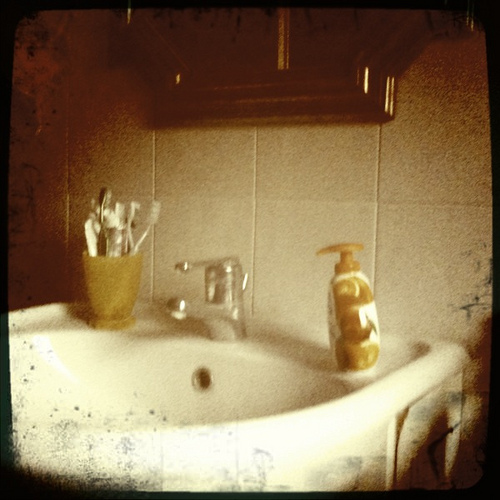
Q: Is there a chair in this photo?
A: No, there are no chairs.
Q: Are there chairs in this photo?
A: No, there are no chairs.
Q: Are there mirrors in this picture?
A: Yes, there is a mirror.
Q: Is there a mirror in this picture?
A: Yes, there is a mirror.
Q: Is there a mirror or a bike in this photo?
A: Yes, there is a mirror.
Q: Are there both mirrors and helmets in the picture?
A: No, there is a mirror but no helmets.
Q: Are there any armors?
A: No, there are no armors.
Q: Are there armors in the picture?
A: No, there are no armors.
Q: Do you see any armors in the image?
A: No, there are no armors.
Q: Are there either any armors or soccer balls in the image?
A: No, there are no armors or soccer balls.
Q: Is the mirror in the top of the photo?
A: Yes, the mirror is in the top of the image.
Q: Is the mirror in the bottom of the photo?
A: No, the mirror is in the top of the image.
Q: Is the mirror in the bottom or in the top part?
A: The mirror is in the top of the image.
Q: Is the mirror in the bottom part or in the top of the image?
A: The mirror is in the top of the image.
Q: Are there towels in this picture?
A: No, there are no towels.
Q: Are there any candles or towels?
A: No, there are no towels or candles.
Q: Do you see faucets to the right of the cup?
A: Yes, there is a faucet to the right of the cup.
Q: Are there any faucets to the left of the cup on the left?
A: No, the faucet is to the right of the cup.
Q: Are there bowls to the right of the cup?
A: No, there is a faucet to the right of the cup.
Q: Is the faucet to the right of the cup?
A: Yes, the faucet is to the right of the cup.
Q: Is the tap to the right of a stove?
A: No, the tap is to the right of the cup.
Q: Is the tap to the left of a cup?
A: No, the tap is to the right of a cup.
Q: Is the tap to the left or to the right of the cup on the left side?
A: The tap is to the right of the cup.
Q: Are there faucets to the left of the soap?
A: Yes, there is a faucet to the left of the soap.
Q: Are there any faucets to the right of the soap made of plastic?
A: No, the faucet is to the left of the soap.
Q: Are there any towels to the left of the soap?
A: No, there is a faucet to the left of the soap.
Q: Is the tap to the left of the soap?
A: Yes, the tap is to the left of the soap.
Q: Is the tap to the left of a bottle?
A: No, the tap is to the left of the soap.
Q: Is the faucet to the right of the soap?
A: No, the faucet is to the left of the soap.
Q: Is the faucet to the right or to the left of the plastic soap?
A: The faucet is to the left of the soap.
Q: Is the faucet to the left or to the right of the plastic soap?
A: The faucet is to the left of the soap.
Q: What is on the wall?
A: The tiles are on the wall.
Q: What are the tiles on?
A: The tiles are on the wall.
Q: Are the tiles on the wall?
A: Yes, the tiles are on the wall.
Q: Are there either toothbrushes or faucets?
A: Yes, there is a toothbrush.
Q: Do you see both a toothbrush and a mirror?
A: Yes, there are both a toothbrush and a mirror.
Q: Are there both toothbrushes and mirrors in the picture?
A: Yes, there are both a toothbrush and a mirror.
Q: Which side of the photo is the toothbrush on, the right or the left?
A: The toothbrush is on the left of the image.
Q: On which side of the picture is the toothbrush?
A: The toothbrush is on the left of the image.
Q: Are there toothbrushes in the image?
A: Yes, there is a toothbrush.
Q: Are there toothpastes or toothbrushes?
A: Yes, there is a toothbrush.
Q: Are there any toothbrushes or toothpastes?
A: Yes, there is a toothbrush.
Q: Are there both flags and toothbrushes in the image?
A: No, there is a toothbrush but no flags.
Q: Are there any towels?
A: No, there are no towels.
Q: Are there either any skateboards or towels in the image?
A: No, there are no towels or skateboards.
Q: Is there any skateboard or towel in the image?
A: No, there are no towels or skateboards.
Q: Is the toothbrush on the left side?
A: Yes, the toothbrush is on the left of the image.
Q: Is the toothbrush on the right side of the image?
A: No, the toothbrush is on the left of the image.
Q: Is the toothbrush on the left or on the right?
A: The toothbrush is on the left of the image.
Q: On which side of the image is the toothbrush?
A: The toothbrush is on the left of the image.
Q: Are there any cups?
A: Yes, there is a cup.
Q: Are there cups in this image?
A: Yes, there is a cup.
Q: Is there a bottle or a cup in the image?
A: Yes, there is a cup.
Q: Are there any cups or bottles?
A: Yes, there is a cup.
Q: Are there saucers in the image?
A: No, there are no saucers.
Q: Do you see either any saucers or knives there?
A: No, there are no saucers or knives.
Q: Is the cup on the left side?
A: Yes, the cup is on the left of the image.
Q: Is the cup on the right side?
A: No, the cup is on the left of the image.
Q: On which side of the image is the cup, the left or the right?
A: The cup is on the left of the image.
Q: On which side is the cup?
A: The cup is on the left of the image.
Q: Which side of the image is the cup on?
A: The cup is on the left of the image.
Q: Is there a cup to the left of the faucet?
A: Yes, there is a cup to the left of the faucet.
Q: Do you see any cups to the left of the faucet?
A: Yes, there is a cup to the left of the faucet.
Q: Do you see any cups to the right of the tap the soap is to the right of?
A: No, the cup is to the left of the tap.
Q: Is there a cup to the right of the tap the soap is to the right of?
A: No, the cup is to the left of the tap.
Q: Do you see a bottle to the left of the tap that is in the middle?
A: No, there is a cup to the left of the faucet.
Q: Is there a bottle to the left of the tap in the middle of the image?
A: No, there is a cup to the left of the faucet.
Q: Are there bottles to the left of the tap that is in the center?
A: No, there is a cup to the left of the faucet.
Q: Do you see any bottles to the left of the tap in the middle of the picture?
A: No, there is a cup to the left of the faucet.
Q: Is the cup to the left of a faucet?
A: Yes, the cup is to the left of a faucet.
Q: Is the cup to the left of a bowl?
A: No, the cup is to the left of a faucet.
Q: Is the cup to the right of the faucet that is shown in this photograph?
A: No, the cup is to the left of the faucet.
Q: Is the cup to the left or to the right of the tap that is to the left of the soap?
A: The cup is to the left of the tap.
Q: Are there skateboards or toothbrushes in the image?
A: Yes, there is a toothbrush.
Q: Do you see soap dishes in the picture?
A: No, there are no soap dishes.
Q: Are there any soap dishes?
A: No, there are no soap dishes.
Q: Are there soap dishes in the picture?
A: No, there are no soap dishes.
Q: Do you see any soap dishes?
A: No, there are no soap dishes.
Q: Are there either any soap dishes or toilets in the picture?
A: No, there are no soap dishes or toilets.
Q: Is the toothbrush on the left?
A: Yes, the toothbrush is on the left of the image.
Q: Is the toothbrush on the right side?
A: No, the toothbrush is on the left of the image.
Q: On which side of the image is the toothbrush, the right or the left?
A: The toothbrush is on the left of the image.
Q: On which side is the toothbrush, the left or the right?
A: The toothbrush is on the left of the image.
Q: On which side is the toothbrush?
A: The toothbrush is on the left of the image.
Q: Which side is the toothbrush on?
A: The toothbrush is on the left of the image.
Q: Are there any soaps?
A: Yes, there is a soap.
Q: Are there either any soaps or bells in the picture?
A: Yes, there is a soap.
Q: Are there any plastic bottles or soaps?
A: Yes, there is a plastic soap.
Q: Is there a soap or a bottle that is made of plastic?
A: Yes, the soap is made of plastic.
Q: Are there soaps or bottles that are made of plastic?
A: Yes, the soap is made of plastic.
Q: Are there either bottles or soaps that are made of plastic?
A: Yes, the soap is made of plastic.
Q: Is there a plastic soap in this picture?
A: Yes, there is a soap that is made of plastic.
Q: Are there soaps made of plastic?
A: Yes, there is a soap that is made of plastic.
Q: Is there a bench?
A: No, there are no benches.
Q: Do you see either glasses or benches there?
A: No, there are no benches or glasses.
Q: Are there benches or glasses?
A: No, there are no benches or glasses.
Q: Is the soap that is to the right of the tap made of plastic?
A: Yes, the soap is made of plastic.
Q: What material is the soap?
A: The soap is made of plastic.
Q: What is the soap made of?
A: The soap is made of plastic.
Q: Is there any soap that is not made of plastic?
A: No, there is a soap but it is made of plastic.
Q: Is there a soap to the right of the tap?
A: Yes, there is a soap to the right of the tap.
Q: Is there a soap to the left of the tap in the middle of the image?
A: No, the soap is to the right of the tap.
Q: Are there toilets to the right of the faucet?
A: No, there is a soap to the right of the faucet.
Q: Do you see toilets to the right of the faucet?
A: No, there is a soap to the right of the faucet.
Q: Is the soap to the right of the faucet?
A: Yes, the soap is to the right of the faucet.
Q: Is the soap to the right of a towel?
A: No, the soap is to the right of the faucet.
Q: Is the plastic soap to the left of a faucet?
A: No, the soap is to the right of a faucet.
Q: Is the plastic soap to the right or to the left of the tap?
A: The soap is to the right of the tap.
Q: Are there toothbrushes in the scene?
A: Yes, there is a toothbrush.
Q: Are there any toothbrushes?
A: Yes, there is a toothbrush.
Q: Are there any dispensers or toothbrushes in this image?
A: Yes, there is a toothbrush.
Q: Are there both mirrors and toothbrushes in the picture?
A: Yes, there are both a toothbrush and a mirror.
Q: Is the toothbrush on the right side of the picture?
A: No, the toothbrush is on the left of the image.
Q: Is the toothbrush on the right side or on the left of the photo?
A: The toothbrush is on the left of the image.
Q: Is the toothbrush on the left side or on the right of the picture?
A: The toothbrush is on the left of the image.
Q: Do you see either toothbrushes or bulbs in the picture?
A: Yes, there is a toothbrush.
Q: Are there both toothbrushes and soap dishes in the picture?
A: No, there is a toothbrush but no soap dishes.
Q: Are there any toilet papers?
A: No, there are no toilet papers.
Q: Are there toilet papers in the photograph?
A: No, there are no toilet papers.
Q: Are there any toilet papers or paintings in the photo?
A: No, there are no toilet papers or paintings.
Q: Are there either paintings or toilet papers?
A: No, there are no toilet papers or paintings.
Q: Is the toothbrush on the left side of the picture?
A: Yes, the toothbrush is on the left of the image.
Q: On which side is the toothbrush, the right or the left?
A: The toothbrush is on the left of the image.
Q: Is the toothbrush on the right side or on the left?
A: The toothbrush is on the left of the image.